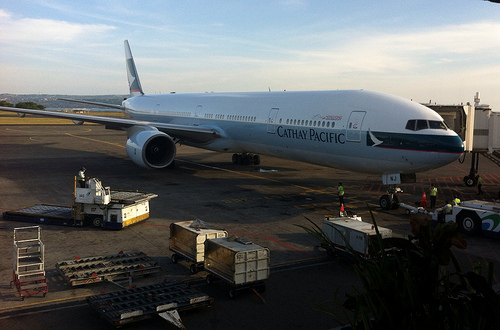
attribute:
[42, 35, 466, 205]
plane — white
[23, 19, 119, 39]
cloud — white, wispy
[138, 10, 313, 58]
sky — blue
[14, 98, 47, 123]
tree — green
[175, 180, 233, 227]
pavement — flat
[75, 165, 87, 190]
man — waiting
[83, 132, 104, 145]
line — yellow